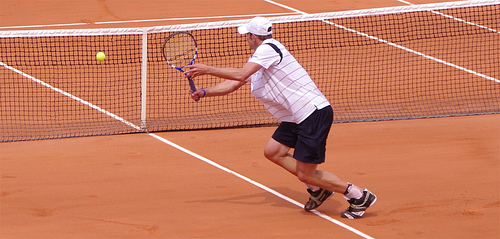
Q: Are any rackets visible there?
A: Yes, there is a racket.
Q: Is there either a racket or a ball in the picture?
A: Yes, there is a racket.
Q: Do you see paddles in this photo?
A: No, there are no paddles.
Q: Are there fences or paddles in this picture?
A: No, there are no paddles or fences.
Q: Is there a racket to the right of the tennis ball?
A: Yes, there is a racket to the right of the tennis ball.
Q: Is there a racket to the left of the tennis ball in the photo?
A: No, the racket is to the right of the tennis ball.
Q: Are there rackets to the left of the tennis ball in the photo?
A: No, the racket is to the right of the tennis ball.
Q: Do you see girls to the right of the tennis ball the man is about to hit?
A: No, there is a racket to the right of the tennis ball.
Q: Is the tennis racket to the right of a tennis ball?
A: Yes, the tennis racket is to the right of a tennis ball.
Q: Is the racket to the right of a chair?
A: No, the racket is to the right of a tennis ball.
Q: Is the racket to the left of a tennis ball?
A: No, the racket is to the right of a tennis ball.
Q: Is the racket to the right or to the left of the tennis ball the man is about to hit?
A: The racket is to the right of the tennis ball.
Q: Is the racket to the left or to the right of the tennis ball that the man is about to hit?
A: The racket is to the right of the tennis ball.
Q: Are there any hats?
A: Yes, there is a hat.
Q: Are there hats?
A: Yes, there is a hat.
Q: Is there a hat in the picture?
A: Yes, there is a hat.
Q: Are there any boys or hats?
A: Yes, there is a hat.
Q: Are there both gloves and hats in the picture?
A: No, there is a hat but no gloves.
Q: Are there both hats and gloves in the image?
A: No, there is a hat but no gloves.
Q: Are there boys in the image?
A: No, there are no boys.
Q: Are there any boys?
A: No, there are no boys.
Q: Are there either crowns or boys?
A: No, there are no boys or crowns.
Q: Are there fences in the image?
A: No, there are no fences.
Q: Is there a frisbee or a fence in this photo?
A: No, there are no fences or frisbees.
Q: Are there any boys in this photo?
A: No, there are no boys.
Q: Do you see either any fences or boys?
A: No, there are no boys or fences.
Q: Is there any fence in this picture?
A: No, there are no fences.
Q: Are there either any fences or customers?
A: No, there are no fences or customers.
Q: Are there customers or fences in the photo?
A: No, there are no fences or customers.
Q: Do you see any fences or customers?
A: No, there are no fences or customers.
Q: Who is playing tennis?
A: The man is playing tennis.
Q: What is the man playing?
A: The man is playing tennis.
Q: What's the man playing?
A: The man is playing tennis.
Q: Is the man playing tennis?
A: Yes, the man is playing tennis.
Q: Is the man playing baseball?
A: No, the man is playing tennis.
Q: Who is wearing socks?
A: The man is wearing socks.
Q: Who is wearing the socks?
A: The man is wearing socks.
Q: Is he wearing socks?
A: Yes, the man is wearing socks.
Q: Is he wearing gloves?
A: No, the man is wearing socks.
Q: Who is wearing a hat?
A: The man is wearing a hat.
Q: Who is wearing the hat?
A: The man is wearing a hat.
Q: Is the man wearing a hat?
A: Yes, the man is wearing a hat.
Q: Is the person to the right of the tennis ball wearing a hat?
A: Yes, the man is wearing a hat.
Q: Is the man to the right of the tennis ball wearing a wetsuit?
A: No, the man is wearing a hat.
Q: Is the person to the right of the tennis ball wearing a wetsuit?
A: No, the man is wearing a hat.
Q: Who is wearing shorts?
A: The man is wearing shorts.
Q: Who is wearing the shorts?
A: The man is wearing shorts.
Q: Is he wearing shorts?
A: Yes, the man is wearing shorts.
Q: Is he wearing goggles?
A: No, the man is wearing shorts.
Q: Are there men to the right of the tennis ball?
A: Yes, there is a man to the right of the tennis ball.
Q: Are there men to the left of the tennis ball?
A: No, the man is to the right of the tennis ball.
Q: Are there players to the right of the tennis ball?
A: No, there is a man to the right of the tennis ball.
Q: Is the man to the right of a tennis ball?
A: Yes, the man is to the right of a tennis ball.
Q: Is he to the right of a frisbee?
A: No, the man is to the right of a tennis ball.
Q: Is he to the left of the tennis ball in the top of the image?
A: No, the man is to the right of the tennis ball.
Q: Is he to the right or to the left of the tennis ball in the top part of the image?
A: The man is to the right of the tennis ball.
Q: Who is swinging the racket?
A: The man is swinging the racket.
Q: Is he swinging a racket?
A: Yes, the man is swinging a racket.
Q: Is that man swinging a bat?
A: No, the man is swinging a racket.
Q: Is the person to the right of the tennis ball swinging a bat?
A: No, the man is swinging a racket.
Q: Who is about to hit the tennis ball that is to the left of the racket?
A: The man is about to hit the tennis ball.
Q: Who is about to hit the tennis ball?
A: The man is about to hit the tennis ball.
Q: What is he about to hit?
A: The man is about to hit the tennis ball.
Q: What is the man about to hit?
A: The man is about to hit the tennis ball.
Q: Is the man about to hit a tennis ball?
A: Yes, the man is about to hit a tennis ball.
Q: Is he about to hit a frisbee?
A: No, the man is about to hit a tennis ball.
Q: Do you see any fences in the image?
A: No, there are no fences.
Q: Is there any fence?
A: No, there are no fences.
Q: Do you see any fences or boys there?
A: No, there are no fences or boys.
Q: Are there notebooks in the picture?
A: No, there are no notebooks.